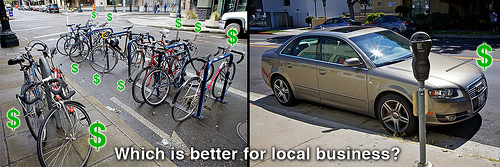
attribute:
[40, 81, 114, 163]
wheel — bicycle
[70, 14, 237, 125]
bicycles — several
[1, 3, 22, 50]
light pole — street, black, metal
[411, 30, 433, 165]
parking meter — pictured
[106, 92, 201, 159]
arrow — white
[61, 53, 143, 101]
signs — dollar, green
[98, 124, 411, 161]
words — white, which is better for local business?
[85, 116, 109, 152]
dollar sign — green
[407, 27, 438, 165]
parking meter — metal, street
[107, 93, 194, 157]
arrow — white, painted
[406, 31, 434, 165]
parking meter — grey, metal, silver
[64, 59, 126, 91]
dollar signs — green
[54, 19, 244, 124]
bikes — parked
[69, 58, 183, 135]
sidewalk — pictured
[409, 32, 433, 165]
meter — parking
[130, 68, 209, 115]
tires — bicycle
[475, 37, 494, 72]
dollar sign — large, green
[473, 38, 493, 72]
sign — dollar, green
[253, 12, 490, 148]
gold car — parked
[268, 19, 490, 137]
car — silver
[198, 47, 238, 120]
guard rail — blue